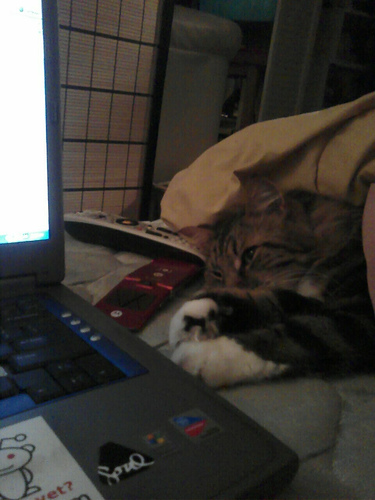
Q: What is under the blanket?
A: Cat.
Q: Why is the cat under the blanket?
A: Sleeping.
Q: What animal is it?
A: Cat.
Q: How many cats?
A: One.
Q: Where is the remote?
A: By the cats head.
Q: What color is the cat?
A: Gray white.